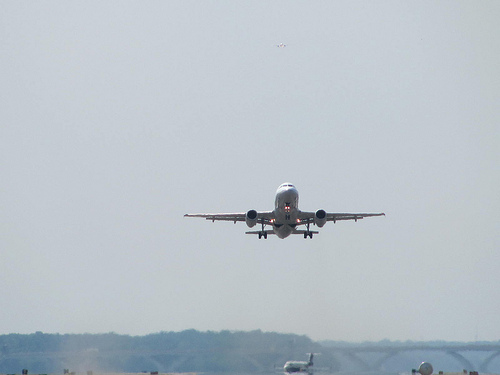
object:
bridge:
[0, 344, 500, 375]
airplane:
[182, 182, 387, 240]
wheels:
[259, 231, 262, 239]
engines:
[245, 209, 259, 228]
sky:
[0, 0, 500, 343]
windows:
[288, 185, 292, 187]